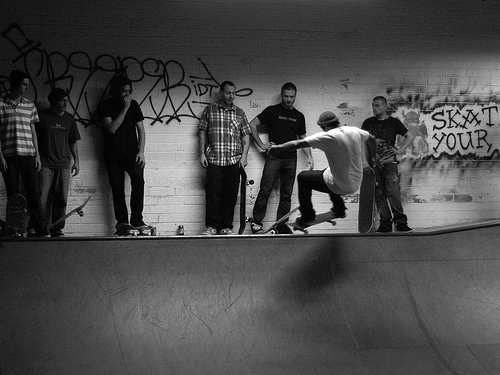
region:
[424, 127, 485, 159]
"Your" written on the wall.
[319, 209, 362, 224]
The skateboard is black.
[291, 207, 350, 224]
Feet on the skateboard.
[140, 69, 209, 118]
Graffiti on the wall.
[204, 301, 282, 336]
The ramp is grey.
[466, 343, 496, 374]
Dark grey patch on the ramp.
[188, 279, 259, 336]
Scuff mark on the ramp.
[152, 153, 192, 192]
The wall is white.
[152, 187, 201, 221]
The wall is made of brick.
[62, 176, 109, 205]
Paint coming off the brick.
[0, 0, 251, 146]
graffiti is on the wall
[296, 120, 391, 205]
man's shirt is white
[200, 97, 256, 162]
man's shirt is plaid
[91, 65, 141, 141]
man is covering his mouth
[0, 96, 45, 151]
man's shirt is striped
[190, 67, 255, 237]
man holding a skateboard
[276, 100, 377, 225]
the man is sktateboarding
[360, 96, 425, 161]
man's hand is on hip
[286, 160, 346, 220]
man's pants are black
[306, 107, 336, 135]
man wearing a hat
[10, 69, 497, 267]
Men stand on side of skateboard ramp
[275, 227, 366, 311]
The ramp has a shadow on it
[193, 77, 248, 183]
One man is wearing a plaid shirt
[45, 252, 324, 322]
The ramp is scratched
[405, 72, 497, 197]
There is graffiti on the wall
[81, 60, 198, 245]
Man bites finger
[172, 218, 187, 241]
A shoe sits on the edge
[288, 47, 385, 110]
The wall is chipping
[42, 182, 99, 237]
The skateboard sitting diagonally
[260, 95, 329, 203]
Man wearing tshirt with wording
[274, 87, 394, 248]
a man in white shirt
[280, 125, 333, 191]
a man in white shirt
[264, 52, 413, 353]
a man in white shirt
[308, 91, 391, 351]
a man in white shirt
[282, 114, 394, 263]
the man in white shirt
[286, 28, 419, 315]
the man in white shirt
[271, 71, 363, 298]
the man in white shirt